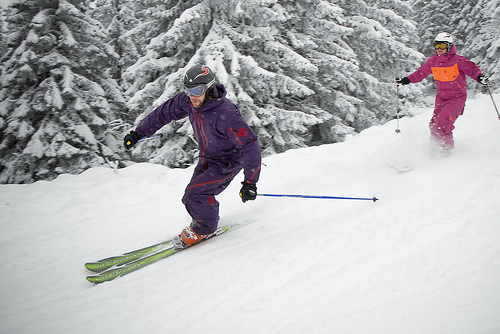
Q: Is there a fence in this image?
A: No, there are no fences.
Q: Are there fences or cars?
A: No, there are no fences or cars.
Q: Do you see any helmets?
A: Yes, there is a helmet.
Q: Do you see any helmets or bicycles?
A: Yes, there is a helmet.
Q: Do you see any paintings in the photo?
A: No, there are no paintings.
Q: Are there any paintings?
A: No, there are no paintings.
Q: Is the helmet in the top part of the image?
A: Yes, the helmet is in the top of the image.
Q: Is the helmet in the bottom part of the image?
A: No, the helmet is in the top of the image.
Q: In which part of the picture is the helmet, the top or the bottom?
A: The helmet is in the top of the image.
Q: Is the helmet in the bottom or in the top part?
A: The helmet is in the top of the image.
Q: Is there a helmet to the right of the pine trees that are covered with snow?
A: Yes, there is a helmet to the right of the pines.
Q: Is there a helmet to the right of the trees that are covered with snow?
A: Yes, there is a helmet to the right of the pines.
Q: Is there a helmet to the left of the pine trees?
A: No, the helmet is to the right of the pine trees.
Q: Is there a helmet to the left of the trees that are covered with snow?
A: No, the helmet is to the right of the pine trees.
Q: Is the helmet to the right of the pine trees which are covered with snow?
A: Yes, the helmet is to the right of the pine trees.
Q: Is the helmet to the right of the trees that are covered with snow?
A: Yes, the helmet is to the right of the pine trees.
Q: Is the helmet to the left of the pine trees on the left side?
A: No, the helmet is to the right of the pine trees.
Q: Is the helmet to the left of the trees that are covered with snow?
A: No, the helmet is to the right of the pine trees.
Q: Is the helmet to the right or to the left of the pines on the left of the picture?
A: The helmet is to the right of the pine trees.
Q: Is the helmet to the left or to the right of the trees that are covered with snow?
A: The helmet is to the right of the pine trees.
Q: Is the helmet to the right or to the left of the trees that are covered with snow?
A: The helmet is to the right of the pine trees.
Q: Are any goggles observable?
A: Yes, there are goggles.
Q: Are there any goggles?
A: Yes, there are goggles.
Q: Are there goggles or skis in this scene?
A: Yes, there are goggles.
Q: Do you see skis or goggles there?
A: Yes, there are goggles.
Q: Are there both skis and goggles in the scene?
A: Yes, there are both goggles and a ski.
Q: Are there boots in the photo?
A: Yes, there are boots.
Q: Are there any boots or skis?
A: Yes, there are boots.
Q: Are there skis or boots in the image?
A: Yes, there are boots.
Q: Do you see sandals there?
A: No, there are no sandals.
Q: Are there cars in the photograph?
A: No, there are no cars.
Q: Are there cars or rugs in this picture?
A: No, there are no cars or rugs.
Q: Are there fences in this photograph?
A: No, there are no fences.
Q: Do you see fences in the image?
A: No, there are no fences.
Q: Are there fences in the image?
A: No, there are no fences.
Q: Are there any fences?
A: No, there are no fences.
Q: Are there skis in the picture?
A: Yes, there are skis.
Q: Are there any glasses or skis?
A: Yes, there are skis.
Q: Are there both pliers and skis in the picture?
A: No, there are skis but no pliers.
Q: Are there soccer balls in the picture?
A: No, there are no soccer balls.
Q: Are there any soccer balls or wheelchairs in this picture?
A: No, there are no soccer balls or wheelchairs.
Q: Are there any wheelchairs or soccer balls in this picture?
A: No, there are no soccer balls or wheelchairs.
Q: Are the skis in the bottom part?
A: Yes, the skis are in the bottom of the image.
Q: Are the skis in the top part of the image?
A: No, the skis are in the bottom of the image.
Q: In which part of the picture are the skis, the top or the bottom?
A: The skis are in the bottom of the image.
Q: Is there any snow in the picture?
A: Yes, there is snow.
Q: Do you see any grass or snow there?
A: Yes, there is snow.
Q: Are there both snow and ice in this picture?
A: No, there is snow but no ice.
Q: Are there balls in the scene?
A: No, there are no balls.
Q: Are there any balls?
A: No, there are no balls.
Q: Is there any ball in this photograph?
A: No, there are no balls.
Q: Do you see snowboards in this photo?
A: No, there are no snowboards.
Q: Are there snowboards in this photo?
A: No, there are no snowboards.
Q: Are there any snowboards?
A: No, there are no snowboards.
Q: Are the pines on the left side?
A: Yes, the pines are on the left of the image.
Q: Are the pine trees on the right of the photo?
A: No, the pine trees are on the left of the image.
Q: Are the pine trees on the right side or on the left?
A: The pine trees are on the left of the image.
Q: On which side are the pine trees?
A: The pine trees are on the left of the image.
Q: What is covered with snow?
A: The pines are covered with snow.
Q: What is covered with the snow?
A: The pines are covered with snow.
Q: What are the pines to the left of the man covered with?
A: The pines are covered with snow.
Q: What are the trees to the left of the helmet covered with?
A: The pines are covered with snow.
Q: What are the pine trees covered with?
A: The pines are covered with snow.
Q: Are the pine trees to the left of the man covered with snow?
A: Yes, the pines are covered with snow.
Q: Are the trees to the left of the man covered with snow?
A: Yes, the pines are covered with snow.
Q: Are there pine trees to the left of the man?
A: Yes, there are pine trees to the left of the man.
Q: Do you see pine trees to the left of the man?
A: Yes, there are pine trees to the left of the man.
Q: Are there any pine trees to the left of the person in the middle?
A: Yes, there are pine trees to the left of the man.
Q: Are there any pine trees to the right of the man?
A: No, the pine trees are to the left of the man.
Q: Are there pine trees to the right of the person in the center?
A: No, the pine trees are to the left of the man.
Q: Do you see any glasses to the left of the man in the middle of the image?
A: No, there are pine trees to the left of the man.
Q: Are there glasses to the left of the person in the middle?
A: No, there are pine trees to the left of the man.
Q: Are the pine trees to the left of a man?
A: Yes, the pine trees are to the left of a man.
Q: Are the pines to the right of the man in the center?
A: No, the pines are to the left of the man.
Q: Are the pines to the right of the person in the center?
A: No, the pines are to the left of the man.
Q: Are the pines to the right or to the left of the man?
A: The pines are to the left of the man.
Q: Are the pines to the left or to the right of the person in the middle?
A: The pines are to the left of the man.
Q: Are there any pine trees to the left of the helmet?
A: Yes, there are pine trees to the left of the helmet.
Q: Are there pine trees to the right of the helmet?
A: No, the pine trees are to the left of the helmet.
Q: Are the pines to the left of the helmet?
A: Yes, the pines are to the left of the helmet.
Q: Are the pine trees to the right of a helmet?
A: No, the pine trees are to the left of a helmet.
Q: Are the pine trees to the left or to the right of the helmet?
A: The pine trees are to the left of the helmet.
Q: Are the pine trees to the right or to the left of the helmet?
A: The pine trees are to the left of the helmet.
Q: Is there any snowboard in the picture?
A: No, there are no snowboards.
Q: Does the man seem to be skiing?
A: Yes, the man is skiing.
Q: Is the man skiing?
A: Yes, the man is skiing.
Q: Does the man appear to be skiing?
A: Yes, the man is skiing.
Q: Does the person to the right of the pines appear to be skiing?
A: Yes, the man is skiing.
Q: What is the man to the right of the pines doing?
A: The man is skiing.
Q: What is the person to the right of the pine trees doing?
A: The man is skiing.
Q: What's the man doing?
A: The man is skiing.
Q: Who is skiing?
A: The man is skiing.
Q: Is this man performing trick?
A: No, the man is skiing.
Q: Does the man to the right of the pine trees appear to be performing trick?
A: No, the man is skiing.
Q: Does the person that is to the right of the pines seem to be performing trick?
A: No, the man is skiing.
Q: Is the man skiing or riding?
A: The man is skiing.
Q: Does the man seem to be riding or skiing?
A: The man is skiing.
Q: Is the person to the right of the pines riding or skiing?
A: The man is skiing.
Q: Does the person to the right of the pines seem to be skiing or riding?
A: The man is skiing.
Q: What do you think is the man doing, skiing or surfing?
A: The man is skiing.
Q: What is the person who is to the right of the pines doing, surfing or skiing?
A: The man is skiing.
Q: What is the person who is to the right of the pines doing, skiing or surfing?
A: The man is skiing.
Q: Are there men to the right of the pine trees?
A: Yes, there is a man to the right of the pine trees.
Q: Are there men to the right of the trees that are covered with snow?
A: Yes, there is a man to the right of the pine trees.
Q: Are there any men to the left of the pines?
A: No, the man is to the right of the pines.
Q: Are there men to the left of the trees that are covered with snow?
A: No, the man is to the right of the pines.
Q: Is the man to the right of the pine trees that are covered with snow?
A: Yes, the man is to the right of the pines.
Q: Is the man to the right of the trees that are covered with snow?
A: Yes, the man is to the right of the pines.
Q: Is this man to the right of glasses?
A: No, the man is to the right of the pines.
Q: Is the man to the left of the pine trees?
A: No, the man is to the right of the pine trees.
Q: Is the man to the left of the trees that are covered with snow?
A: No, the man is to the right of the pine trees.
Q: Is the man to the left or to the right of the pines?
A: The man is to the right of the pines.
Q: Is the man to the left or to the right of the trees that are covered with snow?
A: The man is to the right of the pines.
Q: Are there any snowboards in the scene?
A: No, there are no snowboards.